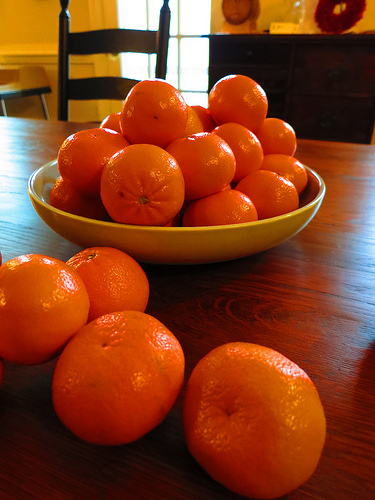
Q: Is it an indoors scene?
A: Yes, it is indoors.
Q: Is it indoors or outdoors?
A: It is indoors.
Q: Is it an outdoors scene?
A: No, it is indoors.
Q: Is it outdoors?
A: No, it is indoors.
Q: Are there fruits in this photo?
A: Yes, there is a fruit.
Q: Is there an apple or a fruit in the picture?
A: Yes, there is a fruit.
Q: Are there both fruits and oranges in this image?
A: Yes, there are both a fruit and oranges.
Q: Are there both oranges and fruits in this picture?
A: Yes, there are both a fruit and oranges.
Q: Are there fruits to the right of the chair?
A: Yes, there is a fruit to the right of the chair.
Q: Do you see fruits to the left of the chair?
A: No, the fruit is to the right of the chair.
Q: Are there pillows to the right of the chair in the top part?
A: No, there is a fruit to the right of the chair.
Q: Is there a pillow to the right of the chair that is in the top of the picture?
A: No, there is a fruit to the right of the chair.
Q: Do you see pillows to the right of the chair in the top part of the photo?
A: No, there is a fruit to the right of the chair.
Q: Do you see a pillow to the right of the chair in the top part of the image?
A: No, there is a fruit to the right of the chair.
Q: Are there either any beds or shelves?
A: No, there are no beds or shelves.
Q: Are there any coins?
A: No, there are no coins.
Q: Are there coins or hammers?
A: No, there are no coins or hammers.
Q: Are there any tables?
A: Yes, there is a table.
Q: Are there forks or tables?
A: Yes, there is a table.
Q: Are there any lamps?
A: No, there are no lamps.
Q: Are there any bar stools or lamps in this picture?
A: No, there are no lamps or bar stools.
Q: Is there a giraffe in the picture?
A: No, there are no giraffes.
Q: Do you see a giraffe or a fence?
A: No, there are no giraffes or fences.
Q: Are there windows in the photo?
A: Yes, there is a window.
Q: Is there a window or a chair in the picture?
A: Yes, there is a window.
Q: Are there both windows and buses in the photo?
A: No, there is a window but no buses.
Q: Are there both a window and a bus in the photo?
A: No, there is a window but no buses.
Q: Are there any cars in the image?
A: No, there are no cars.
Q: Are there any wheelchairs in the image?
A: No, there are no wheelchairs.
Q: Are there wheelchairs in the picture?
A: No, there are no wheelchairs.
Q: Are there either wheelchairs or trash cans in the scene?
A: No, there are no wheelchairs or trash cans.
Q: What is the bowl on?
A: The bowl is on the table.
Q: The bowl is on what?
A: The bowl is on the table.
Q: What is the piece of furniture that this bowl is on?
A: The piece of furniture is a table.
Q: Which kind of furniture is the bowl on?
A: The bowl is on the table.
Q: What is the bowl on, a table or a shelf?
A: The bowl is on a table.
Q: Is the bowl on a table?
A: Yes, the bowl is on a table.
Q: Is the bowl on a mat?
A: No, the bowl is on a table.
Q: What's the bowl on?
A: The bowl is on the table.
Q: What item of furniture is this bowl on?
A: The bowl is on the table.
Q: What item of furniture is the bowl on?
A: The bowl is on the table.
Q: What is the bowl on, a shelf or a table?
A: The bowl is on a table.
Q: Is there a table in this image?
A: Yes, there is a table.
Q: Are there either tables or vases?
A: Yes, there is a table.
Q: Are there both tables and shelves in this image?
A: No, there is a table but no shelves.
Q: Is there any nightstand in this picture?
A: No, there are no nightstands.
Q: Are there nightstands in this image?
A: No, there are no nightstands.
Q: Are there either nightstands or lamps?
A: No, there are no nightstands or lamps.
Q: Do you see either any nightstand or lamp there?
A: No, there are no nightstands or lamps.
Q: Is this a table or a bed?
A: This is a table.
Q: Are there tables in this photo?
A: Yes, there is a table.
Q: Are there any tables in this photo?
A: Yes, there is a table.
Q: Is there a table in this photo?
A: Yes, there is a table.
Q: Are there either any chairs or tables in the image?
A: Yes, there is a table.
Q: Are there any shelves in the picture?
A: No, there are no shelves.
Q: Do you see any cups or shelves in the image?
A: No, there are no shelves or cups.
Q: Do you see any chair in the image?
A: Yes, there is a chair.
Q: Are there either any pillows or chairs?
A: Yes, there is a chair.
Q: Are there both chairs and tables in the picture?
A: Yes, there are both a chair and a table.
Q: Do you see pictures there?
A: No, there are no pictures.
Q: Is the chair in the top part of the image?
A: Yes, the chair is in the top of the image.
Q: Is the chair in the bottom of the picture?
A: No, the chair is in the top of the image.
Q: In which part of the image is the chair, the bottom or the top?
A: The chair is in the top of the image.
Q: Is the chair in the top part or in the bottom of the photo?
A: The chair is in the top of the image.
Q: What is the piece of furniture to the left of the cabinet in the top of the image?
A: The piece of furniture is a chair.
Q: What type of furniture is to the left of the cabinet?
A: The piece of furniture is a chair.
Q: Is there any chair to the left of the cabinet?
A: Yes, there is a chair to the left of the cabinet.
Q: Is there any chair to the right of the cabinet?
A: No, the chair is to the left of the cabinet.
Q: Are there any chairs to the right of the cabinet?
A: No, the chair is to the left of the cabinet.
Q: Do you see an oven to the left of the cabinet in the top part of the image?
A: No, there is a chair to the left of the cabinet.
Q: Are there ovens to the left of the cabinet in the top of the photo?
A: No, there is a chair to the left of the cabinet.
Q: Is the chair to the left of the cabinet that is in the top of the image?
A: Yes, the chair is to the left of the cabinet.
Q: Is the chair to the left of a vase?
A: No, the chair is to the left of the cabinet.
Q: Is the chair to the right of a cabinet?
A: No, the chair is to the left of a cabinet.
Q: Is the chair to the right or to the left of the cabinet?
A: The chair is to the left of the cabinet.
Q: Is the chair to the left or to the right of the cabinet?
A: The chair is to the left of the cabinet.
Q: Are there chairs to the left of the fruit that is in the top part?
A: Yes, there is a chair to the left of the fruit.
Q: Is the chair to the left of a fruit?
A: Yes, the chair is to the left of a fruit.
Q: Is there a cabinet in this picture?
A: Yes, there is a cabinet.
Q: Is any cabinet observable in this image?
A: Yes, there is a cabinet.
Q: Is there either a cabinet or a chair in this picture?
A: Yes, there is a cabinet.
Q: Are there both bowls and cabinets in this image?
A: Yes, there are both a cabinet and a bowl.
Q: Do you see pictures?
A: No, there are no pictures.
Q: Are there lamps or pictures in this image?
A: No, there are no pictures or lamps.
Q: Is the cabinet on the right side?
A: Yes, the cabinet is on the right of the image.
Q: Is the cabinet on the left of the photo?
A: No, the cabinet is on the right of the image.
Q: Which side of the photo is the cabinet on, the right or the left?
A: The cabinet is on the right of the image.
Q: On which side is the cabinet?
A: The cabinet is on the right of the image.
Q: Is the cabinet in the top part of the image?
A: Yes, the cabinet is in the top of the image.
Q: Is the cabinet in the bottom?
A: No, the cabinet is in the top of the image.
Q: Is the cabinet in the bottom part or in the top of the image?
A: The cabinet is in the top of the image.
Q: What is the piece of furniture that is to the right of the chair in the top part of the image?
A: The piece of furniture is a cabinet.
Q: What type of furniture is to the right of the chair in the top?
A: The piece of furniture is a cabinet.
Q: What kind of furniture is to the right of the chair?
A: The piece of furniture is a cabinet.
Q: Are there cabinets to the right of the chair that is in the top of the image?
A: Yes, there is a cabinet to the right of the chair.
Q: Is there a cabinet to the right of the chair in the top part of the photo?
A: Yes, there is a cabinet to the right of the chair.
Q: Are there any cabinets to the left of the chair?
A: No, the cabinet is to the right of the chair.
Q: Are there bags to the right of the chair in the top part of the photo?
A: No, there is a cabinet to the right of the chair.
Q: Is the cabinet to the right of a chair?
A: Yes, the cabinet is to the right of a chair.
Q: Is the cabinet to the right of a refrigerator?
A: No, the cabinet is to the right of a chair.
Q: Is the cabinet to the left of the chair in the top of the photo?
A: No, the cabinet is to the right of the chair.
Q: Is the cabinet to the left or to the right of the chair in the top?
A: The cabinet is to the right of the chair.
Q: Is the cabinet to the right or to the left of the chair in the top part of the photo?
A: The cabinet is to the right of the chair.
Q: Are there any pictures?
A: No, there are no pictures.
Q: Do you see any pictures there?
A: No, there are no pictures.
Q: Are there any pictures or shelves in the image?
A: No, there are no pictures or shelves.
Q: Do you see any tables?
A: Yes, there is a table.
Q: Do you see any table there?
A: Yes, there is a table.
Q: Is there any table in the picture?
A: Yes, there is a table.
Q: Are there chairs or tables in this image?
A: Yes, there is a table.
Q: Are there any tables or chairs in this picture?
A: Yes, there is a table.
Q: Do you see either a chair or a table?
A: Yes, there is a table.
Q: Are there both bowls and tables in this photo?
A: Yes, there are both a table and a bowl.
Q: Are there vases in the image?
A: No, there are no vases.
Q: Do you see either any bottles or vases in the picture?
A: No, there are no vases or bottles.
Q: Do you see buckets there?
A: No, there are no buckets.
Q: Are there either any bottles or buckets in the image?
A: No, there are no buckets or bottles.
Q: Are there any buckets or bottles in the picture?
A: No, there are no buckets or bottles.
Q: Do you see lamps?
A: No, there are no lamps.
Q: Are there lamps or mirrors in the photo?
A: No, there are no lamps or mirrors.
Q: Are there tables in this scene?
A: Yes, there is a table.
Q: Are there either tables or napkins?
A: Yes, there is a table.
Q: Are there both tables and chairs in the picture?
A: Yes, there are both a table and a chair.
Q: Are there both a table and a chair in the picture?
A: Yes, there are both a table and a chair.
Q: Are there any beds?
A: No, there are no beds.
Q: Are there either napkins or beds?
A: No, there are no beds or napkins.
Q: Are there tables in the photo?
A: Yes, there is a table.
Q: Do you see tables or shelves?
A: Yes, there is a table.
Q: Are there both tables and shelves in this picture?
A: No, there is a table but no shelves.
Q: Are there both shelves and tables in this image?
A: No, there is a table but no shelves.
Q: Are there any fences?
A: No, there are no fences.